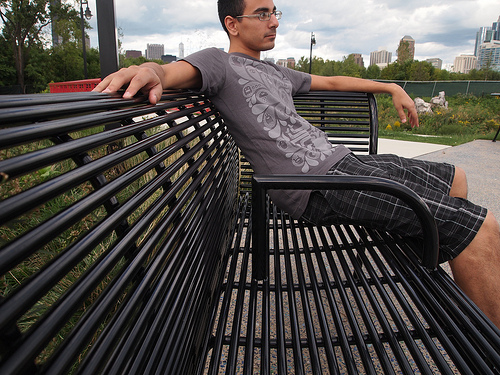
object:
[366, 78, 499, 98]
fence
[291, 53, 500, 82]
treeline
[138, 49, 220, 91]
arm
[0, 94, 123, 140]
pipe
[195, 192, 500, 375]
bottom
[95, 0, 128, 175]
pole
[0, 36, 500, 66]
horizon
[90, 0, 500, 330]
man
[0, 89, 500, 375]
bench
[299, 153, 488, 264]
shorts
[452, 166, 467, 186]
knee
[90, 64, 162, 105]
hand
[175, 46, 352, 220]
shirt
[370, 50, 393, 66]
building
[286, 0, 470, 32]
sky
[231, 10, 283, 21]
glasses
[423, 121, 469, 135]
grass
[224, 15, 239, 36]
ear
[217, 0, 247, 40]
hair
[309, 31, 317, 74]
light post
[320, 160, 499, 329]
leg